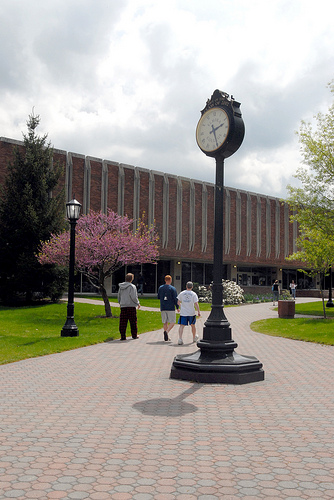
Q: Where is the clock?
A: Sidewalk.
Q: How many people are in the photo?
A: Five.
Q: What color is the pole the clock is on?
A: Black.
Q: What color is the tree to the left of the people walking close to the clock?
A: Pink.